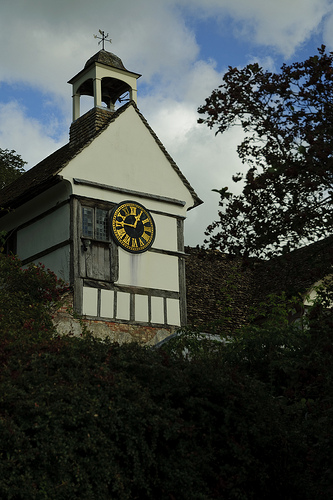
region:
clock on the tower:
[110, 198, 153, 252]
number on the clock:
[130, 238, 138, 249]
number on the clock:
[130, 206, 137, 217]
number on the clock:
[141, 224, 152, 233]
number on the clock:
[113, 219, 124, 228]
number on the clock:
[113, 211, 124, 222]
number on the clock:
[121, 205, 128, 217]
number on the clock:
[142, 215, 152, 224]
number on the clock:
[140, 233, 150, 241]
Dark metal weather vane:
[91, 26, 113, 48]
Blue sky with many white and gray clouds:
[4, 1, 330, 256]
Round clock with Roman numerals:
[108, 199, 156, 253]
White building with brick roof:
[4, 25, 200, 335]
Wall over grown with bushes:
[7, 316, 331, 498]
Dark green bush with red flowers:
[1, 250, 76, 355]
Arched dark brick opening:
[255, 231, 332, 342]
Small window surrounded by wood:
[69, 193, 123, 282]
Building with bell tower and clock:
[4, 25, 204, 334]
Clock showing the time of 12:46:
[104, 196, 158, 255]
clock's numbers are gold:
[118, 207, 150, 254]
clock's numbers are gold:
[101, 202, 163, 254]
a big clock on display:
[100, 197, 161, 267]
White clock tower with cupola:
[2, 27, 204, 347]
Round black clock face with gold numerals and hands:
[107, 199, 157, 255]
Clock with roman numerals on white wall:
[107, 199, 156, 254]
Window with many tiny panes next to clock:
[72, 193, 120, 284]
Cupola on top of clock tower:
[67, 48, 141, 109]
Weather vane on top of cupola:
[92, 28, 113, 49]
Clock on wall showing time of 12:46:
[108, 198, 157, 255]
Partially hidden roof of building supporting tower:
[183, 233, 331, 338]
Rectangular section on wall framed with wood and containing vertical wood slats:
[72, 277, 188, 331]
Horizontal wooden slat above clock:
[73, 176, 187, 209]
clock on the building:
[109, 198, 160, 256]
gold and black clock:
[103, 199, 160, 252]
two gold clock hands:
[111, 209, 147, 231]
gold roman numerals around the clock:
[107, 199, 163, 255]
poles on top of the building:
[88, 22, 115, 50]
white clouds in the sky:
[1, 1, 330, 255]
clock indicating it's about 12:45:
[103, 197, 175, 259]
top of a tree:
[181, 43, 332, 270]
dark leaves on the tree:
[195, 38, 332, 257]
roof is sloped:
[0, 99, 214, 216]